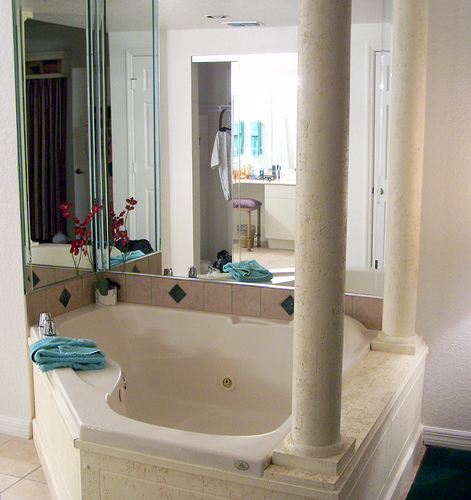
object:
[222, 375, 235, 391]
drain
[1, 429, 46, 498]
tile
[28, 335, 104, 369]
blue towel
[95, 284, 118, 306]
cup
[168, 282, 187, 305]
triangle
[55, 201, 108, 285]
plant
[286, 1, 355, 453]
column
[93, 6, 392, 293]
mirror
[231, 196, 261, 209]
cushion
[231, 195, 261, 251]
stool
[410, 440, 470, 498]
rug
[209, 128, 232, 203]
shirt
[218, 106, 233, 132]
hanger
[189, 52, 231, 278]
closet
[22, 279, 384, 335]
tiling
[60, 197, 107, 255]
flowers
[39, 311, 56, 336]
knobs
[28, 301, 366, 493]
jicuzzi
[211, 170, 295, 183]
sink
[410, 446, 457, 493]
tile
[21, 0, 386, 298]
reflection